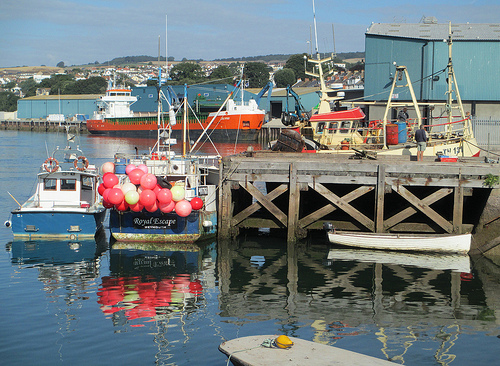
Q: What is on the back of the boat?
A: Balloons.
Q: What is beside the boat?
A: The dock.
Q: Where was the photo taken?
A: At a boat dock.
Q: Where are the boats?
A: In the water.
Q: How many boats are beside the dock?
A: Two.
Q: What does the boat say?
A: Royal Escape.